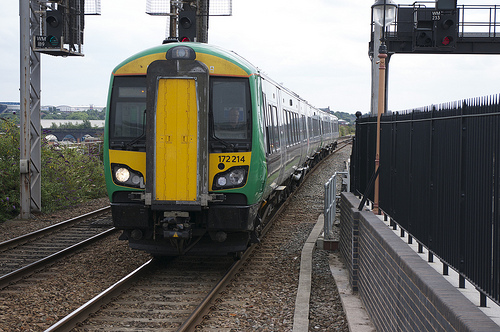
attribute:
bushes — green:
[0, 115, 107, 220]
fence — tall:
[350, 92, 499, 309]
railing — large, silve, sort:
[320, 167, 342, 233]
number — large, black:
[216, 153, 246, 163]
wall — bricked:
[341, 210, 492, 329]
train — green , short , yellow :
[101, 43, 340, 264]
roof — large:
[37, 117, 106, 129]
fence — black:
[341, 92, 498, 319]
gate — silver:
[299, 166, 356, 253]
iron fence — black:
[351, 109, 490, 188]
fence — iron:
[359, 99, 464, 230]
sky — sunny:
[0, 5, 493, 123]